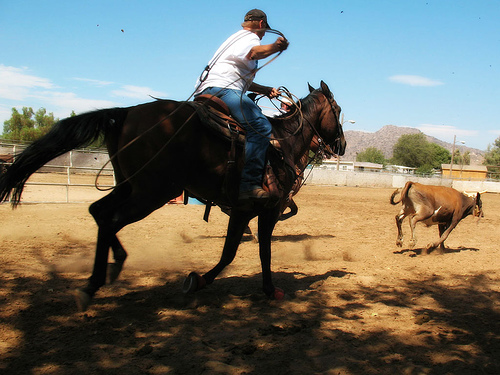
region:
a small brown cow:
[390, 180, 482, 255]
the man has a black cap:
[241, 5, 271, 30]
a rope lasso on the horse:
[92, 52, 277, 189]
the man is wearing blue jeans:
[206, 85, 273, 182]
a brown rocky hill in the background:
[345, 124, 499, 164]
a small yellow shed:
[441, 162, 486, 182]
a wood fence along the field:
[315, 168, 403, 187]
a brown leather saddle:
[193, 94, 235, 125]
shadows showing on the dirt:
[1, 273, 498, 373]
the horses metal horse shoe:
[178, 270, 200, 296]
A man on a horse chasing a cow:
[3, 5, 494, 364]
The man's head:
[241, 7, 273, 41]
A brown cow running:
[383, 178, 485, 257]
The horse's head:
[304, 75, 351, 157]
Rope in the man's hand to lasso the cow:
[91, 21, 307, 197]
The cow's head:
[469, 188, 486, 221]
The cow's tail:
[388, 178, 413, 208]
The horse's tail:
[2, 102, 111, 214]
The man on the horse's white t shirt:
[192, 25, 259, 95]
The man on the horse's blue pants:
[191, 85, 277, 204]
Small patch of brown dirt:
[35, 324, 110, 366]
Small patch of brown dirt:
[117, 327, 187, 368]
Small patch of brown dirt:
[205, 327, 297, 361]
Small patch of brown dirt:
[304, 324, 338, 365]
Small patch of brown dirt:
[343, 324, 390, 362]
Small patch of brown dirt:
[406, 316, 448, 358]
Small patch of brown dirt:
[325, 268, 395, 304]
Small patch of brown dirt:
[405, 256, 475, 320]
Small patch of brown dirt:
[174, 253, 304, 318]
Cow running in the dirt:
[382, 145, 479, 287]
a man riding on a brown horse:
[1, 8, 354, 300]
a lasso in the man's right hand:
[88, 30, 312, 195]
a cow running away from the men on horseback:
[388, 174, 488, 255]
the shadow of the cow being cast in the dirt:
[394, 243, 481, 258]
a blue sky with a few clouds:
[1, 0, 498, 149]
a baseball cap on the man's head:
[246, 5, 268, 23]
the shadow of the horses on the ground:
[0, 227, 360, 344]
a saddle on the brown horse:
[190, 93, 252, 140]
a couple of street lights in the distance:
[338, 114, 467, 171]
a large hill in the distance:
[341, 125, 491, 166]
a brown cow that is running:
[389, 178, 485, 255]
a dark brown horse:
[6, 82, 348, 309]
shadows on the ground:
[0, 230, 499, 369]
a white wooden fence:
[301, 165, 499, 196]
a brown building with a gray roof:
[440, 162, 488, 181]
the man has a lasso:
[94, 7, 306, 214]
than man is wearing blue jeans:
[198, 8, 288, 211]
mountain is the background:
[335, 123, 495, 166]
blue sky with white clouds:
[3, 4, 498, 150]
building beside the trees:
[353, 133, 499, 181]